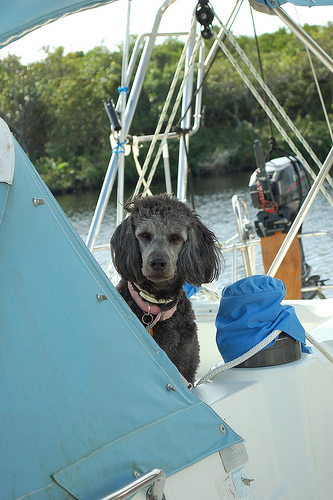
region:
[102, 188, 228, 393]
a grey dog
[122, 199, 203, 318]
a dog wearing a collar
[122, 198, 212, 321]
a dog wearing a fle collar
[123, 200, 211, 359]
a dog wearing a tag on a collar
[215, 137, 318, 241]
a black motor to a boat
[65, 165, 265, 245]
a body of water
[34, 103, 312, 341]
a dog sitting on a boat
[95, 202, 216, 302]
a dog with long ears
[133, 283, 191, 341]
a pink dog collar with a orange tag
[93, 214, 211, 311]
a dog with a black nose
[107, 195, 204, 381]
black poodle dog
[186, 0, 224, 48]
black pulley for the ropes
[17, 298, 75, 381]
part of the blue tarp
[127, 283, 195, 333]
red and yellow collars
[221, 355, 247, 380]
part of the white robe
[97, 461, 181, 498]
silver handle on the hatch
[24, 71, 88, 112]
green trees in the background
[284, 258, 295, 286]
orange wooden board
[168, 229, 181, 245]
eye of the black poodle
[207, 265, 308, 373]
blue cloth covering black object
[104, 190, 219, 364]
An older black dog on a boat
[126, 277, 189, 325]
A faded red dog collar on a black dog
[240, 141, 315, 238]
A boat motor out of the water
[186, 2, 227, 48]
A puller with a rope through it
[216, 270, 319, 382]
A blue cloth covering an object on a boat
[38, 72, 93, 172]
Green trees on the other side of the water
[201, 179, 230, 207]
Mirky water behind the boat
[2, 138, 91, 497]
A blue canvas cover for a boat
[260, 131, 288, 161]
A black rope holding up a motor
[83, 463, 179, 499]
A silver hand railing on a boat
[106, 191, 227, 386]
Poodle in a boat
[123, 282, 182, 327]
Collar around dog's neck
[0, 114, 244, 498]
Blue cover on boat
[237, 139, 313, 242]
Motor on back of boat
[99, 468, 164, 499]
Silver railing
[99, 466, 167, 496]
Silver railing on side of boat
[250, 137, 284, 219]
Propeller on boat's motor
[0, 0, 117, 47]
Blue awning over boat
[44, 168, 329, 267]
Calm blue water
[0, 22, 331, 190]
Greenery on other side of water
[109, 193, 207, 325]
dog with red collar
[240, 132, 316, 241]
outdoor motor on boat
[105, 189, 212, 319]
dog with white flea collar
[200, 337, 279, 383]
a white nylon rope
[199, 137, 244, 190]
water and tree lined shore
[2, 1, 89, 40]
blue awning with white trim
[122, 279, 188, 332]
faded red dog collar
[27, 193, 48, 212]
small metal attachment on canvas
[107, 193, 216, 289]
dog's face with gray hair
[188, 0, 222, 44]
black pulley with rope